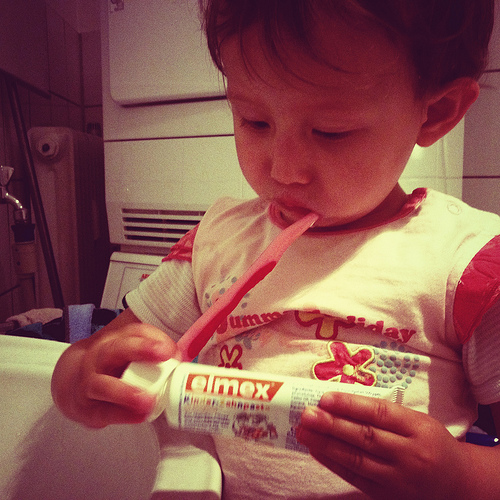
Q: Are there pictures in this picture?
A: No, there are no pictures.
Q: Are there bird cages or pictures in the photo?
A: No, there are no pictures or bird cages.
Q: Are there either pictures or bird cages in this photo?
A: No, there are no pictures or bird cages.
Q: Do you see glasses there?
A: No, there are no glasses.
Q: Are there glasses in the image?
A: No, there are no glasses.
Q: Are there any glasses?
A: No, there are no glasses.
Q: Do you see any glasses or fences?
A: No, there are no glasses or fences.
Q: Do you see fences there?
A: No, there are no fences.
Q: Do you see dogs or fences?
A: No, there are no fences or dogs.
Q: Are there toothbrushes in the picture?
A: Yes, there is a toothbrush.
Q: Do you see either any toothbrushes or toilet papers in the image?
A: Yes, there is a toothbrush.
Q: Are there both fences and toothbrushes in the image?
A: No, there is a toothbrush but no fences.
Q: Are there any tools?
A: No, there are no tools.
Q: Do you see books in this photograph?
A: No, there are no books.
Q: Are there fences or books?
A: No, there are no books or fences.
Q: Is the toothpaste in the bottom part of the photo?
A: Yes, the toothpaste is in the bottom of the image.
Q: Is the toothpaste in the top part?
A: No, the toothpaste is in the bottom of the image.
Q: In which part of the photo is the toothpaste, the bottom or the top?
A: The toothpaste is in the bottom of the image.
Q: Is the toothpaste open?
A: Yes, the toothpaste is open.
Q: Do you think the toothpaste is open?
A: Yes, the toothpaste is open.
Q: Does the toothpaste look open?
A: Yes, the toothpaste is open.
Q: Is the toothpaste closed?
A: No, the toothpaste is open.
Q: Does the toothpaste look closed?
A: No, the toothpaste is open.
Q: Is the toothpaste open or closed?
A: The toothpaste is open.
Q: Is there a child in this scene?
A: Yes, there is a child.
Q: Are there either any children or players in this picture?
A: Yes, there is a child.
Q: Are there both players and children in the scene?
A: No, there is a child but no players.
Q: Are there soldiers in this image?
A: No, there are no soldiers.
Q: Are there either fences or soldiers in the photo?
A: No, there are no soldiers or fences.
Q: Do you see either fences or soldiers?
A: No, there are no soldiers or fences.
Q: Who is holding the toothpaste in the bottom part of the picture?
A: The kid is holding the toothpaste.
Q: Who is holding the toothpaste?
A: The kid is holding the toothpaste.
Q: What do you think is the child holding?
A: The child is holding the toothpaste.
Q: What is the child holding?
A: The child is holding the toothpaste.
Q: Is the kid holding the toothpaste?
A: Yes, the kid is holding the toothpaste.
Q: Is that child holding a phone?
A: No, the child is holding the toothpaste.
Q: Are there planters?
A: No, there are no planters.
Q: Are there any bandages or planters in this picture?
A: No, there are no planters or bandages.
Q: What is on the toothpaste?
A: The drawing is on the toothpaste.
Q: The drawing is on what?
A: The drawing is on the toothpaste.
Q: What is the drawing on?
A: The drawing is on the toothpaste.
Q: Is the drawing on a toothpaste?
A: Yes, the drawing is on a toothpaste.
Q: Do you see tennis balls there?
A: No, there are no tennis balls.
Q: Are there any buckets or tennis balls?
A: No, there are no tennis balls or buckets.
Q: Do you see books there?
A: No, there are no books.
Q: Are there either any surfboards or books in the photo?
A: No, there are no books or surfboards.